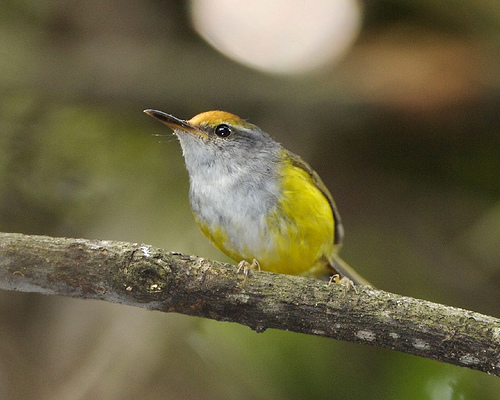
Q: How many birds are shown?
A: One.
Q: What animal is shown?
A: Bird.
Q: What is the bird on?
A: Branch.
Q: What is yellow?
A: Bird.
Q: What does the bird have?
A: Beak.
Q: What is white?
A: Bird's chest.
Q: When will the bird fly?
A: Soon.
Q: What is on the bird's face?
A: Eye.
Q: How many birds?
A: 1.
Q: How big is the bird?
A: Small.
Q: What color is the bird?
A: Yellow.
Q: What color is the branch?
A: Grey.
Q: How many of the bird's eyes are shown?
A: 1.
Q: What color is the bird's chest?
A: Grey.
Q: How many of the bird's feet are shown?
A: 2.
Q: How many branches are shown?
A: 1.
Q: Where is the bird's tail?
A: Behind the branch.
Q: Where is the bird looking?
A: Left.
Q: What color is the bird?
A: Yellow and white.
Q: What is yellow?
A: Feathers.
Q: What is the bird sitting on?
A: Branch.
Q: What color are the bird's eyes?
A: Black.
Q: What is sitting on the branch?
A: A bird.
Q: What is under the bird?
A: Tree Branch.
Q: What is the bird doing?
A: Perching.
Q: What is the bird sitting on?
A: Branch.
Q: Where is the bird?
A: A tree.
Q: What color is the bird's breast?
A: White.